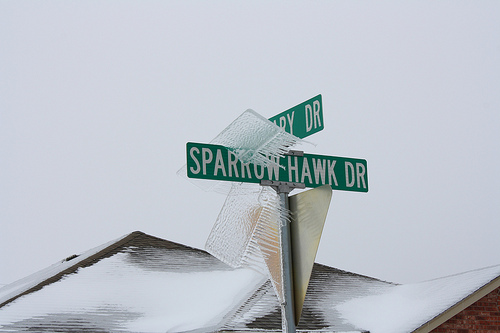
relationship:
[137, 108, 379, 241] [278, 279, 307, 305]
street signs on pole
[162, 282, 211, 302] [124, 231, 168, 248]
snow on roof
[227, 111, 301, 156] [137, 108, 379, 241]
ice on street signs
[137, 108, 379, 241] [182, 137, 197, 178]
street signs has s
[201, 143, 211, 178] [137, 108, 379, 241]
p on street signs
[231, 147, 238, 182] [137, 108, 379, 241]
r on street signs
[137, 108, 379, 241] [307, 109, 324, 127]
street signs have white letters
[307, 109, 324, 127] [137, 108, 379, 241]
white letters on street signs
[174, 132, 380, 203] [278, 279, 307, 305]
street sign on pole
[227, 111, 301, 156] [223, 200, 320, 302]
ice on sign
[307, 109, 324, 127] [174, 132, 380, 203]
white letters on street sign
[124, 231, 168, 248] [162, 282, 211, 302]
roof with snow